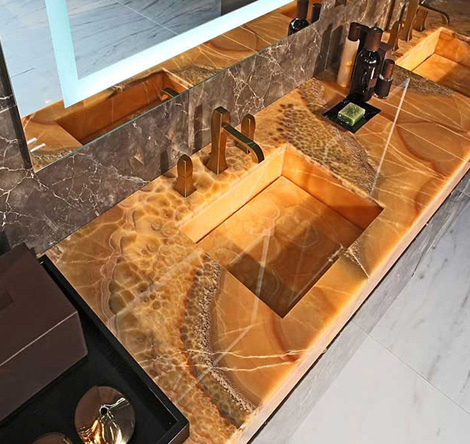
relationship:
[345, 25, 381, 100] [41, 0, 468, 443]
bottle on counter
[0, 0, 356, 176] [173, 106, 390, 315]
mirror above sink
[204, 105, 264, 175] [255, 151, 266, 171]
faucet has water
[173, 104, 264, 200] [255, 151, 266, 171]
faucet has water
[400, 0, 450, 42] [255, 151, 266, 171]
faucet has water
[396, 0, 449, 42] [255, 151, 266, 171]
faucet has water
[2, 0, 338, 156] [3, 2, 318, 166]
mirror wall on wall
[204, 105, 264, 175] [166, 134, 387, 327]
faucet on sink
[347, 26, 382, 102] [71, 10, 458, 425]
bottle on counter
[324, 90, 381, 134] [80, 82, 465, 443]
soapdish on counter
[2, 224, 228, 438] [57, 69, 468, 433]
tray on counter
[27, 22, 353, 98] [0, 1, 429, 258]
mirror on wall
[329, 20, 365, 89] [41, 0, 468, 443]
bottle on counter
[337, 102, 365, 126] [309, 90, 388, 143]
soap on dish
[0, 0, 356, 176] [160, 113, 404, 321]
mirror above sink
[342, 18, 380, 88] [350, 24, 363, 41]
bottle with cap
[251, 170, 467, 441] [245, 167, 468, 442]
tiles on ground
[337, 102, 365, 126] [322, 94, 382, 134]
soap on dish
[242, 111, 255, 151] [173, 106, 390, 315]
knob on sink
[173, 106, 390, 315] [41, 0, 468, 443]
sink on counter